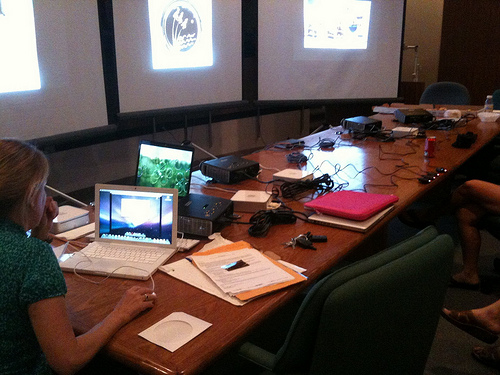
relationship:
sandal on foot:
[440, 303, 500, 346] [444, 303, 498, 336]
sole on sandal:
[440, 303, 500, 346] [440, 303, 500, 346]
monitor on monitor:
[89, 181, 179, 246] [89, 181, 179, 246]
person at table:
[399, 179, 500, 291] [36, 99, 496, 372]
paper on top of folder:
[187, 247, 294, 295] [195, 239, 306, 302]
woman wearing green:
[2, 138, 155, 373] [1, 221, 69, 374]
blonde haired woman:
[1, 140, 50, 225] [2, 138, 155, 373]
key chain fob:
[286, 231, 327, 254] [309, 227, 327, 248]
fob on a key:
[309, 227, 327, 248] [286, 231, 327, 254]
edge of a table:
[399, 78, 429, 109] [402, 78, 425, 105]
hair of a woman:
[1, 140, 50, 225] [2, 138, 155, 373]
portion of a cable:
[241, 171, 326, 198] [246, 165, 293, 199]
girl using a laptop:
[2, 138, 155, 373] [61, 180, 177, 279]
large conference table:
[56, 103, 499, 375] [36, 99, 496, 372]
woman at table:
[2, 138, 155, 373] [36, 99, 496, 372]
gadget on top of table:
[288, 150, 306, 164] [36, 99, 496, 372]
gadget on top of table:
[416, 173, 432, 185] [36, 99, 496, 372]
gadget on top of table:
[322, 137, 334, 149] [36, 99, 496, 372]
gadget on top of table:
[450, 131, 478, 149] [36, 99, 496, 372]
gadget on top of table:
[397, 110, 435, 126] [36, 99, 496, 372]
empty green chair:
[239, 216, 454, 373] [240, 225, 453, 375]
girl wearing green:
[2, 138, 155, 373] [1, 221, 69, 374]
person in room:
[399, 179, 500, 291] [1, 0, 499, 373]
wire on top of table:
[373, 134, 419, 158] [36, 99, 496, 372]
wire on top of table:
[338, 170, 417, 196] [36, 99, 496, 372]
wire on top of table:
[245, 166, 279, 193] [36, 99, 496, 372]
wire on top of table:
[303, 134, 324, 153] [36, 99, 496, 372]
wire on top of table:
[189, 180, 241, 196] [36, 99, 496, 372]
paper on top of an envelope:
[187, 247, 294, 295] [195, 239, 306, 302]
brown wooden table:
[56, 103, 499, 375] [36, 99, 496, 372]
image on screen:
[302, 2, 370, 56] [253, 0, 403, 97]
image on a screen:
[146, 2, 219, 74] [105, 1, 249, 121]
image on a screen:
[4, 0, 44, 95] [2, 1, 110, 145]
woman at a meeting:
[2, 138, 155, 373] [1, 141, 498, 349]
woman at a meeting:
[440, 288, 500, 374] [1, 141, 498, 349]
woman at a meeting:
[399, 179, 500, 291] [1, 141, 498, 349]